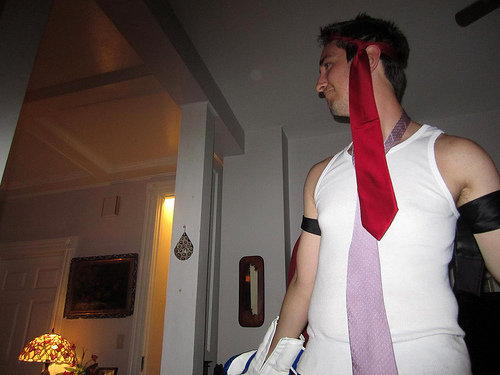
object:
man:
[223, 14, 498, 375]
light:
[160, 196, 176, 224]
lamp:
[17, 331, 78, 375]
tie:
[329, 32, 400, 243]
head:
[313, 12, 410, 121]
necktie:
[345, 108, 413, 375]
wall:
[0, 100, 499, 372]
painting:
[63, 251, 141, 321]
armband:
[298, 214, 322, 238]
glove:
[220, 313, 307, 374]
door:
[0, 235, 76, 375]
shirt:
[295, 122, 473, 346]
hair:
[317, 11, 411, 107]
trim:
[24, 62, 167, 118]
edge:
[124, 178, 166, 372]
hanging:
[173, 224, 195, 262]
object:
[238, 257, 266, 328]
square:
[101, 194, 120, 217]